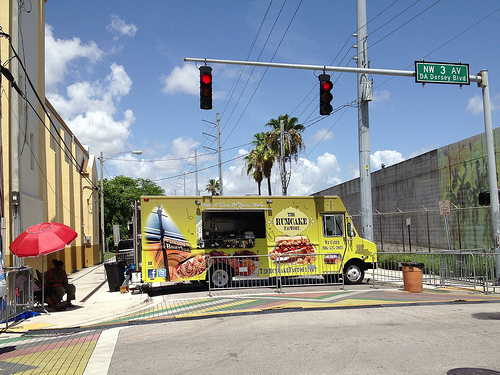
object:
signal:
[199, 66, 213, 109]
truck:
[134, 195, 378, 288]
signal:
[318, 74, 334, 115]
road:
[1, 288, 498, 375]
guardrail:
[207, 252, 500, 296]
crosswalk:
[79, 285, 497, 329]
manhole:
[446, 367, 500, 375]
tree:
[264, 113, 306, 196]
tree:
[251, 130, 279, 196]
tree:
[244, 149, 262, 196]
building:
[0, 0, 102, 278]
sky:
[43, 1, 500, 54]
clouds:
[42, 14, 136, 159]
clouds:
[108, 138, 340, 197]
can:
[104, 261, 125, 292]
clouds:
[370, 149, 405, 171]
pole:
[183, 57, 415, 76]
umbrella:
[9, 222, 78, 259]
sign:
[415, 60, 471, 85]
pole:
[357, 0, 374, 243]